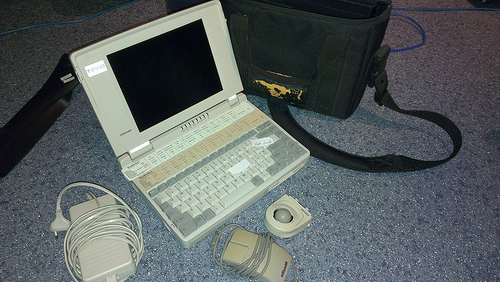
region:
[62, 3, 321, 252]
old opened gray laptop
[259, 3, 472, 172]
black nylon bag with strap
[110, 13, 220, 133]
blank black screen on laptop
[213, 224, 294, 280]
mouse wrapped in wire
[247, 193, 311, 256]
gray computer trackball next to mouse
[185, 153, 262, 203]
keys on laptop keyboard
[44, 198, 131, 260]
gray electrical cord wrapped around unit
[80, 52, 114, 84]
white label on gray laptop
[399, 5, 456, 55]
blue wire in background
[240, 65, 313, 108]
worn patch on nylon material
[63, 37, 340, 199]
Grey laptop on the floor.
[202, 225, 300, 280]
Mouse for the computer.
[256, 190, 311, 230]
The roller ball on the floor.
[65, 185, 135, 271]
The power cord wrapped next to the floor.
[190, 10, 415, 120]
The black bag next to the computer.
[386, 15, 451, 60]
The blue cord behind the black bag.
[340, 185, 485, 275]
The empty floor in front of the computer.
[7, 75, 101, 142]
The black straps behind the laptop.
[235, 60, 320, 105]
The yellow object in the side bag.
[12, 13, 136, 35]
Blue cord behind the laptop.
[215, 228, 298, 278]
computer mouse and cord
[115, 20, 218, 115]
part of computer screen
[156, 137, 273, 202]
part of keyboard area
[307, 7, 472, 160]
portion of black bag and strap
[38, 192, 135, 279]
white adapter unit with cord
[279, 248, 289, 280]
Writing on mouse pad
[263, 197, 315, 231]
tracking ball for computer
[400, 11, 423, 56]
part of a blue cord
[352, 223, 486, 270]
portion of blue flooring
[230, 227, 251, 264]
buttons on mouse unit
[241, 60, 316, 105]
A worn computer case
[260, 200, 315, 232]
A visible track ball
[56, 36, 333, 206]
An old laptop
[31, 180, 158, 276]
The battery pack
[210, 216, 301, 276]
A two button mouse with the cord wrapped around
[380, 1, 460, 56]
Blue wire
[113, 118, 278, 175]
Shortcut labels for the keyboard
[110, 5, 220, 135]
A dark and empty screen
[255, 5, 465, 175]
A black bag with an attached strap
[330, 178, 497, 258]
Gray flooring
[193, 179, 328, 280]
Grey plastic computer mouse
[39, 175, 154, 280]
Grey computer power supply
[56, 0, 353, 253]
Very old grey laptop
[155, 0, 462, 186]
Black bag made of cloth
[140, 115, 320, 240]
Grey laptop keyboard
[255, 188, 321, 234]
Grey plastic computer trackball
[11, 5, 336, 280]
Old laptop computer with accessories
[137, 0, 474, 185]
Black cloth laptop bag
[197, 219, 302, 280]
Very old computer mouse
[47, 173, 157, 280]
Very old computer power supply